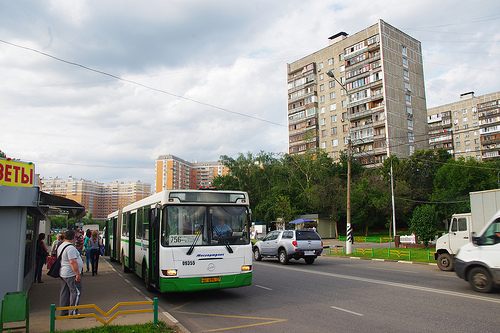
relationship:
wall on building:
[380, 20, 428, 157] [422, 90, 498, 161]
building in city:
[284, 18, 428, 169] [81, 2, 468, 330]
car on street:
[251, 227, 323, 264] [99, 248, 499, 330]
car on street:
[452, 209, 497, 300] [161, 252, 496, 330]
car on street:
[251, 227, 327, 265] [161, 252, 496, 330]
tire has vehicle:
[253, 248, 262, 261] [254, 228, 323, 265]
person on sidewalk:
[88, 228, 102, 276] [2, 251, 189, 331]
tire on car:
[253, 247, 262, 261] [251, 227, 327, 265]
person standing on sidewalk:
[57, 231, 86, 313] [91, 266, 156, 331]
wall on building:
[0, 209, 18, 291] [3, 160, 81, 330]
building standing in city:
[284, 20, 426, 165] [2, 16, 484, 327]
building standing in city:
[426, 85, 498, 165] [2, 16, 484, 327]